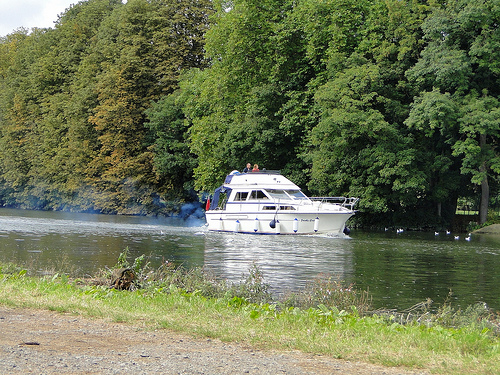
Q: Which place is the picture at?
A: It is at the river.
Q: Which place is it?
A: It is a river.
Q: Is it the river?
A: Yes, it is the river.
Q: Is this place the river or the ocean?
A: It is the river.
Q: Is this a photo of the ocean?
A: No, the picture is showing the river.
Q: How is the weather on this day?
A: It is clear.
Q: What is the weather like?
A: It is clear.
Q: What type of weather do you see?
A: It is clear.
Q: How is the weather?
A: It is clear.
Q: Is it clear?
A: Yes, it is clear.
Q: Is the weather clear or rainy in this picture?
A: It is clear.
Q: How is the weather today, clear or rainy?
A: It is clear.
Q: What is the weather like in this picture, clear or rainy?
A: It is clear.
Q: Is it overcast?
A: No, it is clear.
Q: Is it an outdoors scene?
A: Yes, it is outdoors.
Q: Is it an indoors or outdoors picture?
A: It is outdoors.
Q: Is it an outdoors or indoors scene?
A: It is outdoors.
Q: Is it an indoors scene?
A: No, it is outdoors.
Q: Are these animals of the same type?
A: Yes, all the animals are ducks.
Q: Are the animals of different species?
A: No, all the animals are ducks.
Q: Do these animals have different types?
A: No, all the animals are ducks.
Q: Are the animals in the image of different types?
A: No, all the animals are ducks.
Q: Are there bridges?
A: No, there are no bridges.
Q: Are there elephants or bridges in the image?
A: No, there are no bridges or elephants.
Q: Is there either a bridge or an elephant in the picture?
A: No, there are no bridges or elephants.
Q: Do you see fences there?
A: No, there are no fences.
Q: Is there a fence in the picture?
A: No, there are no fences.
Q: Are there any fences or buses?
A: No, there are no fences or buses.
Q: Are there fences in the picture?
A: No, there are no fences.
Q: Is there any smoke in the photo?
A: Yes, there is smoke.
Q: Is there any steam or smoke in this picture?
A: Yes, there is smoke.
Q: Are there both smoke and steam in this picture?
A: No, there is smoke but no steam.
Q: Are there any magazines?
A: No, there are no magazines.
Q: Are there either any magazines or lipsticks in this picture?
A: No, there are no magazines or lipsticks.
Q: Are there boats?
A: Yes, there is a boat.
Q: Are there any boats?
A: Yes, there is a boat.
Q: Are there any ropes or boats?
A: Yes, there is a boat.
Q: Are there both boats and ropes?
A: No, there is a boat but no ropes.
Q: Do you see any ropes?
A: No, there are no ropes.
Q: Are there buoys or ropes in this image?
A: No, there are no ropes or buoys.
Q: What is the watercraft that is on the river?
A: The watercraft is a boat.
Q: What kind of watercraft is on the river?
A: The watercraft is a boat.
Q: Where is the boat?
A: The boat is on the river.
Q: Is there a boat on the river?
A: Yes, there is a boat on the river.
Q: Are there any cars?
A: No, there are no cars.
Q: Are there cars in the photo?
A: No, there are no cars.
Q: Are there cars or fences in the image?
A: No, there are no cars or fences.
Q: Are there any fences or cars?
A: No, there are no cars or fences.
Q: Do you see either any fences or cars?
A: No, there are no cars or fences.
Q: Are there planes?
A: No, there are no planes.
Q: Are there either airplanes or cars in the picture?
A: No, there are no airplanes or cars.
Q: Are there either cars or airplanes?
A: No, there are no airplanes or cars.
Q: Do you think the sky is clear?
A: Yes, the sky is clear.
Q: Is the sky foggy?
A: No, the sky is clear.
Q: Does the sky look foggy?
A: No, the sky is clear.